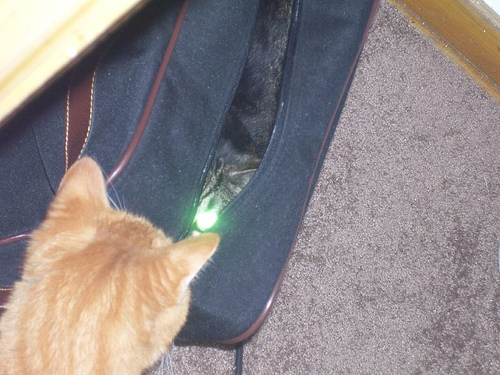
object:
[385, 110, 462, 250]
carpeted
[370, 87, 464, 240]
carpeted floor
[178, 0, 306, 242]
zipper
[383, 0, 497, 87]
wall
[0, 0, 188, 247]
lining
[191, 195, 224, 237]
light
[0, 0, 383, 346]
bag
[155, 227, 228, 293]
ear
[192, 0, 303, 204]
cat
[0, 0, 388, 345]
luggage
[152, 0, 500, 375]
rug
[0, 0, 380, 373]
case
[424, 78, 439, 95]
green patch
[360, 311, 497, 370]
carpet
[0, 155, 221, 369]
head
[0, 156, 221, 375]
cat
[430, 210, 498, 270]
patch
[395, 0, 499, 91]
baseboard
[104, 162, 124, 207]
whiskers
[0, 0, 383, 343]
back back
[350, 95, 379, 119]
brown patch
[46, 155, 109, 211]
ear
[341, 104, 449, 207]
floor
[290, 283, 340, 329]
patch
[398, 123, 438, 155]
patch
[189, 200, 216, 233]
eye